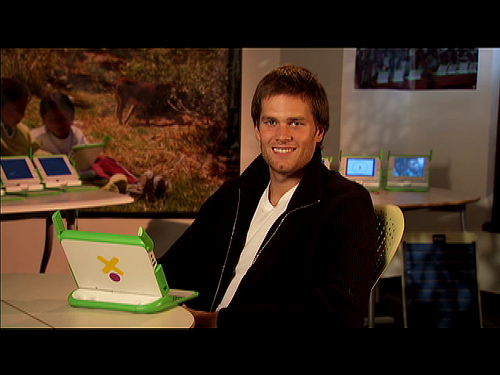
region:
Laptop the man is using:
[45, 209, 195, 311]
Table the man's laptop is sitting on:
[1, 273, 194, 332]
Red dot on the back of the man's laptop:
[108, 271, 122, 284]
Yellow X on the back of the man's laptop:
[93, 251, 128, 278]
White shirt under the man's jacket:
[215, 178, 302, 309]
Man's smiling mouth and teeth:
[267, 142, 304, 160]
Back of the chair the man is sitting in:
[376, 201, 402, 276]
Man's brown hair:
[251, 61, 333, 123]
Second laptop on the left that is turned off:
[33, 155, 85, 188]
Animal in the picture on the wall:
[109, 71, 194, 129]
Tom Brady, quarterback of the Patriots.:
[205, 50, 401, 369]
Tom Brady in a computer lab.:
[1, 32, 488, 363]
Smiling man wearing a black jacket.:
[131, 48, 393, 325]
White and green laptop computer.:
[37, 209, 208, 316]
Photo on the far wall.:
[0, 58, 249, 224]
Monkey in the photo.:
[85, 70, 198, 137]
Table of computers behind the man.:
[248, 134, 480, 218]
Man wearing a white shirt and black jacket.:
[167, 27, 394, 330]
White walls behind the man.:
[213, 51, 493, 294]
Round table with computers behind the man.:
[239, 160, 481, 230]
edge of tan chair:
[380, 196, 415, 253]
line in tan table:
[9, 300, 64, 335]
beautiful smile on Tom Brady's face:
[253, 138, 315, 158]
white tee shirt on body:
[233, 175, 343, 264]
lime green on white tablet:
[47, 282, 179, 332]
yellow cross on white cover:
[90, 251, 130, 288]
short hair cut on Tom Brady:
[233, 60, 390, 117]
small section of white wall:
[368, 93, 482, 131]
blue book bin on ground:
[393, 225, 493, 328]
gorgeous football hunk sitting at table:
[118, 63, 411, 370]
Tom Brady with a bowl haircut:
[245, 60, 338, 192]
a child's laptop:
[45, 206, 210, 319]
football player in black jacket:
[153, 60, 383, 350]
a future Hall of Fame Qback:
[147, 62, 384, 371]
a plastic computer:
[43, 213, 200, 313]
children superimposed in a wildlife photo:
[0, 50, 210, 149]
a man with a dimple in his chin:
[227, 53, 337, 196]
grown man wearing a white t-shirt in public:
[182, 58, 341, 340]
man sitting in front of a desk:
[11, 60, 418, 352]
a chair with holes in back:
[350, 196, 414, 328]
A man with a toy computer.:
[218, 76, 360, 194]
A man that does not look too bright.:
[223, 65, 396, 237]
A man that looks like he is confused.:
[8, 107, 393, 317]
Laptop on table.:
[46, 205, 193, 342]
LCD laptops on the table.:
[332, 150, 469, 180]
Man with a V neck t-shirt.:
[139, 72, 379, 319]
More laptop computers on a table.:
[13, 131, 90, 230]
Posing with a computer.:
[28, 77, 403, 369]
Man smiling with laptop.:
[211, 56, 441, 331]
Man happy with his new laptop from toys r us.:
[29, 79, 356, 367]